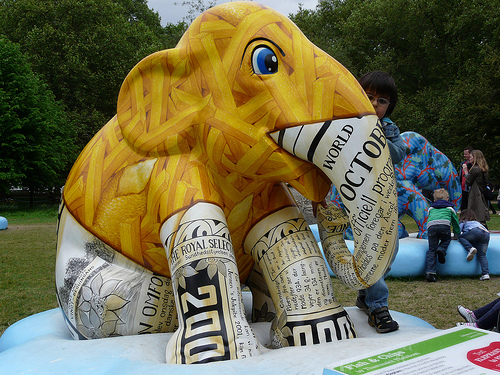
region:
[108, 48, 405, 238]
large yellow elephant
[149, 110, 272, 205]
pattern on elephant looks like french fries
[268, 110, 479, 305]
elephant has newspaper trunk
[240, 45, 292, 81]
elephant has blue eyes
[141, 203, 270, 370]
elephant has newspaper legs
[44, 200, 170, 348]
elephant has a newspaper diaper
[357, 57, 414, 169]
child wearing glasses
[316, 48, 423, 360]
child standing next to elephant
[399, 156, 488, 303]
kinds in the background climbing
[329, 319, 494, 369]
sign in front of elephant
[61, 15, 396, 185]
yellow and brown elephant sculpture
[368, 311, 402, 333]
tennis shoe on boy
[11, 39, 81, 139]
green trees in background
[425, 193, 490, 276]
children climbing on sculpture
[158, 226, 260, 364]
words on elephant leg sculpture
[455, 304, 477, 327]
white tennis shoes on person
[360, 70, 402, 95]
boy with brown hair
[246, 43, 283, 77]
elephants blue eye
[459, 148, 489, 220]
man and woman looking at sculpture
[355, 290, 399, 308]
boys jeans are blue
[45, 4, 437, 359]
yellow elephant with writing on it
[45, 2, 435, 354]
yellow elephant with blue eyes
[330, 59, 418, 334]
boy wearing eyeglasses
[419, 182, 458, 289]
boy wearing long jeans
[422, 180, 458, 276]
boy wearing green sweater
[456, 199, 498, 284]
girl wearing purple shirt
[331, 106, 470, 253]
blue elephant with leaves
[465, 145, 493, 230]
woman wearing black coat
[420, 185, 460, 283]
boy with blue hoodie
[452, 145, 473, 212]
man wearing red shirt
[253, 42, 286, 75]
Elephant has blue eye.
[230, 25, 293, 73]
Elephant has black eyebrow.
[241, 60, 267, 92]
Elephant has black eyelashes.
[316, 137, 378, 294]
Elephant has writing on trunk.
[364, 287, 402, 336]
Person wearing black and gray shoes.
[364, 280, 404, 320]
Person wearing blue pants.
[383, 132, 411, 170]
Person wearing gray coat.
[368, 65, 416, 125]
Person has dark hair.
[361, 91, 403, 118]
Glasses on person's face.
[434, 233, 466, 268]
Person has blue jeans on.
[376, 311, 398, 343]
part of a shoe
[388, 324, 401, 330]
side of a shoe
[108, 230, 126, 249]
part of an elephant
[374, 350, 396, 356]
part of a book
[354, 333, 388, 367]
edge of a book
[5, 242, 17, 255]
part of a lawn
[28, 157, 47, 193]
part of a forest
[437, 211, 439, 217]
back of a man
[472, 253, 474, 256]
part of a sole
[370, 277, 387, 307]
part of a jeans